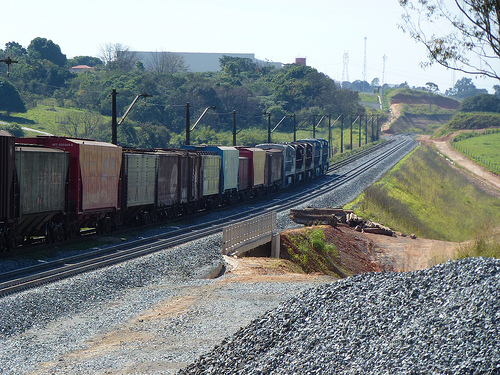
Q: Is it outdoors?
A: Yes, it is outdoors.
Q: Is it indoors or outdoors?
A: It is outdoors.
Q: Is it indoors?
A: No, it is outdoors.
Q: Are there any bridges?
A: Yes, there is a bridge.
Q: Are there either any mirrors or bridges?
A: Yes, there is a bridge.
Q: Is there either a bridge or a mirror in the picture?
A: Yes, there is a bridge.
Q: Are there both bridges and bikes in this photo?
A: No, there is a bridge but no bikes.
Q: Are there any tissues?
A: No, there are no tissues.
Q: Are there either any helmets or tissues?
A: No, there are no tissues or helmets.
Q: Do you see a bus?
A: No, there are no buses.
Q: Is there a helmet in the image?
A: No, there are no helmets.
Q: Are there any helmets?
A: No, there are no helmets.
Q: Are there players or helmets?
A: No, there are no helmets or players.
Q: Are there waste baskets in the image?
A: No, there are no waste baskets.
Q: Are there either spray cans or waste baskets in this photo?
A: No, there are no waste baskets or spray cans.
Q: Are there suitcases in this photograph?
A: No, there are no suitcases.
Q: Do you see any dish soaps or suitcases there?
A: No, there are no suitcases or dish soaps.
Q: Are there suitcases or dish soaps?
A: No, there are no suitcases or dish soaps.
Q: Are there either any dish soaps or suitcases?
A: No, there are no suitcases or dish soaps.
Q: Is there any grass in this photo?
A: Yes, there is grass.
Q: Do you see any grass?
A: Yes, there is grass.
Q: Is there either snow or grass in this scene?
A: Yes, there is grass.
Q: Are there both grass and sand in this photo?
A: No, there is grass but no sand.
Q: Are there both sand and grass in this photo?
A: No, there is grass but no sand.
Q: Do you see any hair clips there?
A: No, there are no hair clips.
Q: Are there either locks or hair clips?
A: No, there are no hair clips or locks.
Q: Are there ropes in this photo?
A: No, there are no ropes.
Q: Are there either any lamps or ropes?
A: No, there are no ropes or lamps.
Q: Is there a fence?
A: Yes, there is a fence.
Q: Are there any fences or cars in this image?
A: Yes, there is a fence.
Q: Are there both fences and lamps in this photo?
A: No, there is a fence but no lamps.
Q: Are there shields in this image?
A: No, there are no shields.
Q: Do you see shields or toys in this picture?
A: No, there are no shields or toys.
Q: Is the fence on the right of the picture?
A: Yes, the fence is on the right of the image.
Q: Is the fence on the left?
A: No, the fence is on the right of the image.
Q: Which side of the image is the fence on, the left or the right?
A: The fence is on the right of the image.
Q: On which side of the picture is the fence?
A: The fence is on the right of the image.